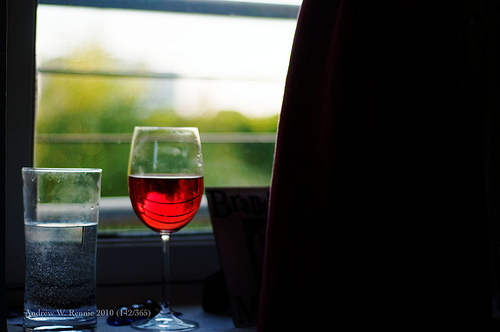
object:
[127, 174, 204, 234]
wine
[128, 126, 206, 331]
glass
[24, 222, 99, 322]
water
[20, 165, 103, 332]
glass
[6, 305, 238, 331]
table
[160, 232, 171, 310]
stem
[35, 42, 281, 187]
trees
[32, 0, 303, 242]
window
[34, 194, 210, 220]
bar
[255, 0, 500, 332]
chair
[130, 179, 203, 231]
reflection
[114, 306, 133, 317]
bead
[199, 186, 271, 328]
frame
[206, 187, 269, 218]
letters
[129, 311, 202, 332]
base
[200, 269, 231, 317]
support